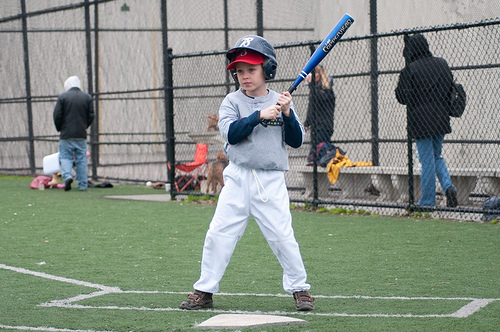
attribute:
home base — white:
[195, 309, 306, 327]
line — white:
[0, 264, 113, 290]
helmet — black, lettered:
[226, 34, 277, 80]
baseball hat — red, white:
[227, 50, 262, 69]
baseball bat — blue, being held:
[261, 12, 354, 127]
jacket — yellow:
[326, 147, 373, 183]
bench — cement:
[297, 165, 497, 206]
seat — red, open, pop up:
[175, 142, 210, 194]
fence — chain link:
[2, 1, 497, 221]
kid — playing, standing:
[179, 33, 313, 315]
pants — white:
[193, 160, 314, 293]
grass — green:
[2, 173, 500, 329]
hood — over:
[65, 74, 82, 90]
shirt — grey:
[218, 87, 304, 173]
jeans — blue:
[307, 132, 330, 165]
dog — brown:
[207, 151, 227, 191]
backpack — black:
[450, 81, 466, 115]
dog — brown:
[206, 110, 221, 132]